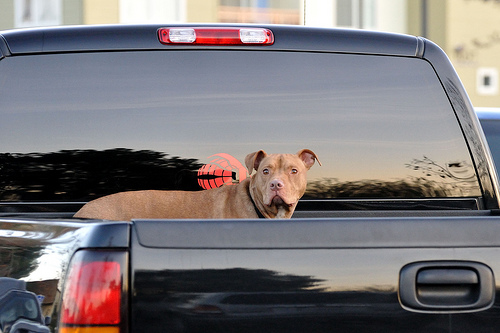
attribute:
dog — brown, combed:
[72, 150, 321, 220]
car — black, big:
[1, 25, 500, 332]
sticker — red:
[198, 151, 246, 192]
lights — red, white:
[158, 26, 277, 46]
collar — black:
[246, 183, 266, 219]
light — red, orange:
[58, 252, 122, 327]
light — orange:
[57, 325, 119, 333]